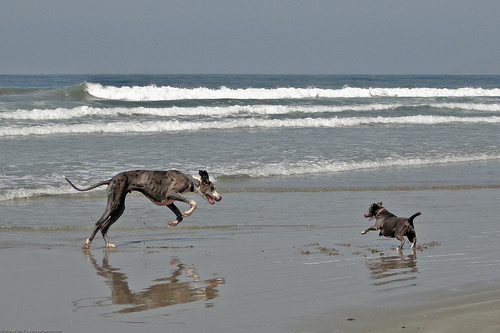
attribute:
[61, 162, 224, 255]
dog — bigger, on the left, running, on low water, small, in water, big, large, grey hound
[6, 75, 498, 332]
beach — wet, paw-printed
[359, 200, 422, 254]
dog — smaller, on the right, little, small, terrier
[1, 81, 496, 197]
ocean — in background, large, in distance, blue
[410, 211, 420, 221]
tail — stubbie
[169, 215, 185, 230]
front foot — off ground, in air, folded back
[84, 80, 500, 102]
wave — white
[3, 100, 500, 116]
wave — small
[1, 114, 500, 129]
wave — small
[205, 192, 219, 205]
mouth — open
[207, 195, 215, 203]
inside — red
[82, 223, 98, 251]
rear paw — in water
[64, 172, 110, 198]
tail — sticking out, long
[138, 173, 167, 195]
ribs — protruding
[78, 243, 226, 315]
shadow — in water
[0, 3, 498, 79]
sky — blue